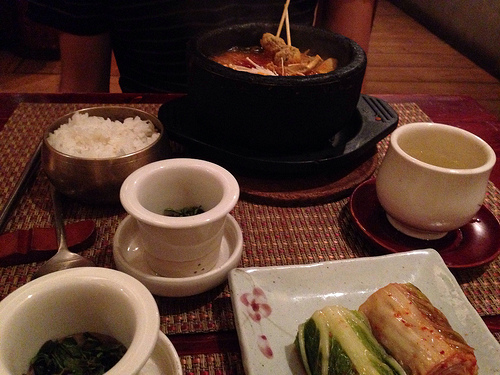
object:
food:
[354, 281, 480, 375]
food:
[25, 331, 126, 375]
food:
[42, 110, 163, 158]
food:
[295, 303, 406, 375]